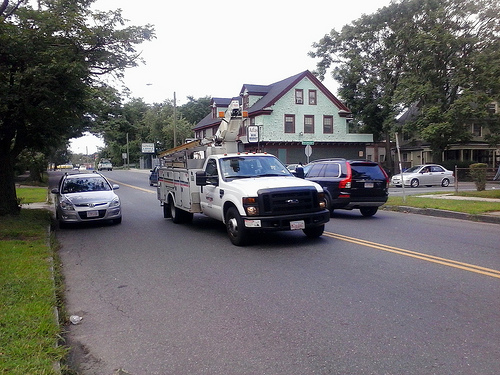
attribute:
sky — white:
[122, 13, 252, 100]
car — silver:
[377, 153, 453, 196]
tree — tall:
[7, 3, 87, 220]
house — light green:
[234, 65, 370, 164]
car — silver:
[44, 160, 131, 255]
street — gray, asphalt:
[55, 168, 499, 371]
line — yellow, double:
[321, 231, 499, 280]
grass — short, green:
[0, 184, 61, 374]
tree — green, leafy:
[1, 2, 159, 210]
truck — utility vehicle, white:
[148, 96, 335, 248]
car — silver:
[50, 170, 124, 226]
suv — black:
[295, 156, 392, 220]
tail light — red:
[341, 175, 355, 190]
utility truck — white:
[148, 97, 338, 245]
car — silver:
[49, 166, 127, 228]